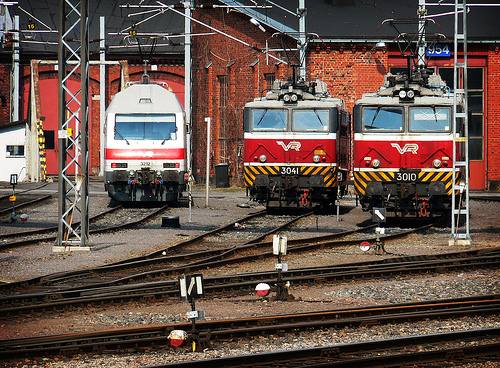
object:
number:
[275, 159, 306, 180]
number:
[390, 167, 419, 184]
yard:
[3, 6, 500, 368]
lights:
[311, 155, 320, 163]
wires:
[102, 11, 177, 65]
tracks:
[0, 300, 500, 368]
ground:
[0, 213, 500, 368]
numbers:
[421, 38, 453, 59]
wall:
[0, 18, 499, 188]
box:
[155, 212, 185, 230]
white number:
[394, 170, 417, 182]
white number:
[278, 164, 301, 175]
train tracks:
[0, 204, 141, 250]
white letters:
[276, 137, 303, 152]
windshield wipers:
[248, 98, 329, 136]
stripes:
[425, 172, 439, 184]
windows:
[403, 102, 460, 139]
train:
[100, 68, 193, 202]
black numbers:
[140, 161, 150, 167]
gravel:
[235, 230, 445, 355]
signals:
[174, 272, 207, 304]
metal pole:
[53, 1, 95, 254]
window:
[113, 119, 148, 143]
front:
[100, 83, 186, 186]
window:
[138, 113, 178, 146]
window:
[245, 105, 291, 135]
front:
[241, 99, 347, 194]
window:
[291, 106, 329, 140]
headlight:
[258, 154, 268, 163]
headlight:
[430, 159, 442, 168]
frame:
[224, 144, 337, 176]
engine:
[229, 70, 356, 209]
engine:
[354, 68, 454, 222]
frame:
[354, 156, 473, 213]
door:
[16, 52, 180, 181]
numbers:
[133, 155, 158, 170]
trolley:
[347, 176, 451, 222]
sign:
[413, 28, 463, 63]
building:
[0, 0, 497, 198]